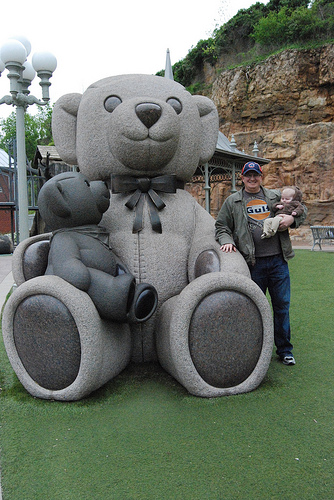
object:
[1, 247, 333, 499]
grass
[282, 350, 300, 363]
sneakers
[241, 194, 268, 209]
bow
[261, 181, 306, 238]
baby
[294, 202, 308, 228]
arm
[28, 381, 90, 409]
dent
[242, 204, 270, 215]
word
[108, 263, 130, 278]
spot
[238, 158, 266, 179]
cap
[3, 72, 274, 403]
bear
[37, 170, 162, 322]
bear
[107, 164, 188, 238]
bow tie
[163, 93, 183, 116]
eyes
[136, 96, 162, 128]
nose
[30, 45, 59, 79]
bulb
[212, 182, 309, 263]
jacket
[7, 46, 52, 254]
post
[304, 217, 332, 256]
bench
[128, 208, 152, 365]
center stitching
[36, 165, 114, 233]
upturned head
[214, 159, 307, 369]
dad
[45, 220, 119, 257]
neckerchief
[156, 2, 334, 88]
vegetation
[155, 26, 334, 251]
mountain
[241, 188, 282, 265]
shirt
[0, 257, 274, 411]
lap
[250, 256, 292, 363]
jeans